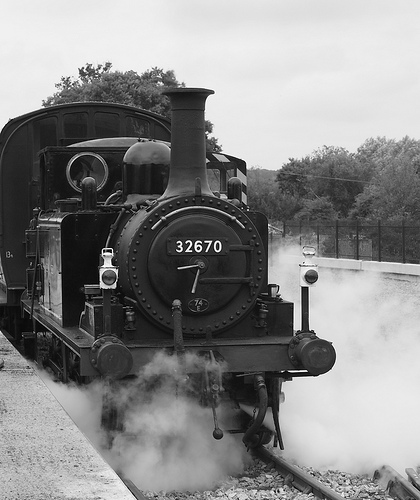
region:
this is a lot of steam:
[85, 350, 249, 492]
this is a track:
[236, 429, 279, 479]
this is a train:
[53, 43, 233, 293]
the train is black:
[106, 148, 253, 422]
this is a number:
[182, 233, 286, 270]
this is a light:
[101, 239, 137, 302]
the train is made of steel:
[246, 369, 360, 471]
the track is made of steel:
[253, 425, 323, 483]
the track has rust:
[239, 418, 277, 487]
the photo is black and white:
[148, 287, 271, 413]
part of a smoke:
[144, 407, 169, 427]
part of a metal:
[212, 411, 222, 427]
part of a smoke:
[158, 421, 200, 473]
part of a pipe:
[237, 368, 274, 437]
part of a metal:
[13, 433, 34, 468]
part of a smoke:
[178, 446, 220, 476]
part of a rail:
[21, 417, 67, 492]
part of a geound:
[238, 470, 265, 493]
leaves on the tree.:
[109, 78, 139, 91]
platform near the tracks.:
[25, 431, 61, 480]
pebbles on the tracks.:
[239, 482, 267, 493]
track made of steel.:
[300, 480, 326, 492]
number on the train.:
[170, 237, 221, 252]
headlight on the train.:
[103, 265, 115, 283]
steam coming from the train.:
[339, 400, 385, 430]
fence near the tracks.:
[351, 233, 382, 246]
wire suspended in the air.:
[281, 167, 339, 189]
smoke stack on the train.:
[173, 89, 209, 176]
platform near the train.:
[28, 456, 72, 475]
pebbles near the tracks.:
[262, 483, 280, 492]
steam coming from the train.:
[340, 421, 367, 440]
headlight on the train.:
[94, 267, 123, 291]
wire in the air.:
[300, 165, 360, 191]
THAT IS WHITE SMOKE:
[136, 463, 146, 487]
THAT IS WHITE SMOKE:
[168, 441, 195, 474]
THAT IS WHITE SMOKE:
[144, 390, 162, 441]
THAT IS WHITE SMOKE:
[132, 402, 177, 474]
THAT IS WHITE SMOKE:
[75, 381, 87, 411]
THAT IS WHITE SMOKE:
[342, 378, 372, 414]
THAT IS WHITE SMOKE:
[303, 381, 336, 459]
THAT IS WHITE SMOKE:
[330, 285, 390, 312]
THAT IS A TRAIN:
[42, 81, 324, 390]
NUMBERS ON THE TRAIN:
[171, 235, 223, 251]